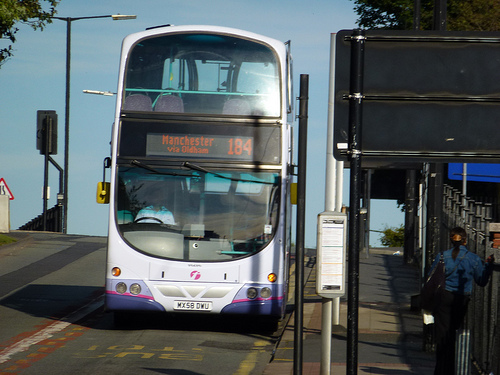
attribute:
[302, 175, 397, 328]
sign — metal, bus route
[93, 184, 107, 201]
side mirror — yellow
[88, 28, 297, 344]
bus — white, blue, black, orange, yellow, red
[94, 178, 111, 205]
mirror — yellow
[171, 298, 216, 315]
license plate — white and black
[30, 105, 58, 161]
traffic light — tall, black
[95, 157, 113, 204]
mirror — yellow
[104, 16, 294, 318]
bus — tall, white, double decker, white and purple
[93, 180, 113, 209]
mirror — yellow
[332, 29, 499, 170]
sign — back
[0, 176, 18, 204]
sign — red and white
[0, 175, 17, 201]
border — red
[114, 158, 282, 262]
window — large